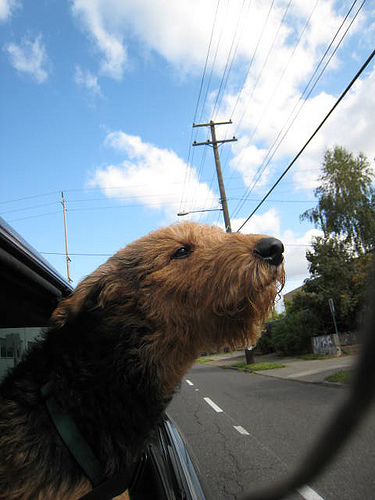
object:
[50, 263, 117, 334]
ear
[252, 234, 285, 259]
nose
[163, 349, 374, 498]
concrete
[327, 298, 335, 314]
sign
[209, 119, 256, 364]
post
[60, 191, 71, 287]
post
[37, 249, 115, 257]
power lines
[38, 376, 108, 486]
collar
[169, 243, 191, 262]
eye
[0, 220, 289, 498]
dog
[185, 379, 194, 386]
line